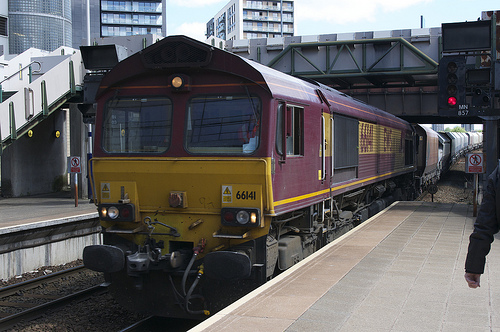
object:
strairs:
[10, 52, 47, 114]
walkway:
[41, 27, 129, 77]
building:
[0, 0, 392, 154]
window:
[102, 12, 157, 26]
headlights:
[93, 192, 269, 230]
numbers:
[234, 188, 258, 203]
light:
[169, 75, 184, 87]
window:
[274, 104, 305, 161]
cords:
[172, 242, 215, 315]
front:
[77, 27, 284, 319]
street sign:
[466, 154, 482, 171]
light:
[249, 210, 258, 224]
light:
[98, 205, 118, 220]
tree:
[441, 125, 468, 134]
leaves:
[439, 121, 467, 133]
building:
[0, 0, 167, 54]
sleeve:
[466, 165, 496, 287]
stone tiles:
[373, 265, 448, 317]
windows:
[82, 0, 165, 36]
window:
[109, 12, 120, 22]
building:
[68, 0, 163, 46]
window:
[271, 0, 278, 8]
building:
[198, 0, 306, 47]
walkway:
[216, 20, 488, 79]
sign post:
[59, 149, 86, 206]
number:
[234, 193, 241, 199]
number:
[239, 188, 246, 198]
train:
[76, 3, 481, 315]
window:
[245, 31, 267, 38]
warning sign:
[462, 145, 487, 176]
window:
[23, 17, 26, 20]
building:
[0, 0, 72, 53]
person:
[459, 149, 499, 288]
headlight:
[224, 205, 264, 231]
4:
[247, 190, 259, 199]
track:
[11, 263, 147, 330]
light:
[447, 96, 462, 106]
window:
[103, 10, 115, 22]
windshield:
[163, 83, 268, 172]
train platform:
[181, 199, 498, 330]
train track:
[112, 307, 155, 330]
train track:
[0, 284, 149, 332]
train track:
[0, 260, 86, 294]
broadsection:
[260, 149, 402, 299]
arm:
[463, 156, 498, 286]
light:
[75, 188, 278, 230]